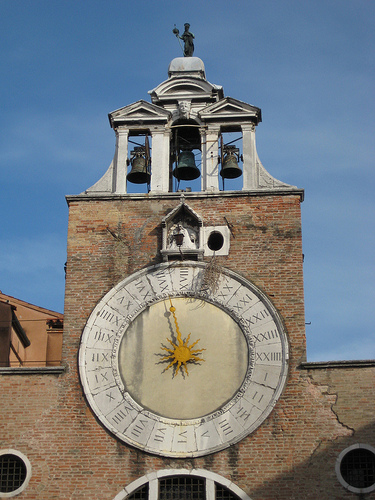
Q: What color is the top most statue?
A: Black.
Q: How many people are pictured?
A: None.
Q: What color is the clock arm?
A: Gold.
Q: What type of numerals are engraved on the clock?
A: Roman.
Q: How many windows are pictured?
A: Five.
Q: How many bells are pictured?
A: Three.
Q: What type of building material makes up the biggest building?
A: Brick.